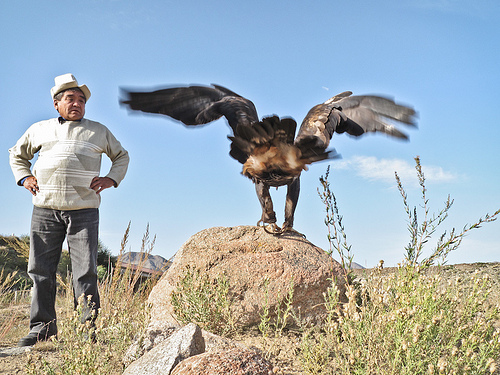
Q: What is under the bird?
A: Giant rock.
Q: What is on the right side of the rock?
A: Grass and plants.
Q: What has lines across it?
A: A white sweater.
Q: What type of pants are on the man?
A: Dark grey jean.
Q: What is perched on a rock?
A: A large bird.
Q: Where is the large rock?
A: On a desert floor.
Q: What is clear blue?
A: Sky.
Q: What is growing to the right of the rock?
A: A desert plant.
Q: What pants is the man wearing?
A: A pair of gray pants.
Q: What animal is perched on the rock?
A: Bird.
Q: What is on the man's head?
A: Hat.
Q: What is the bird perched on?
A: A rock.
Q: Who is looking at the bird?
A: A man.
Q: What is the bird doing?
A: Spreading wings.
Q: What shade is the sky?
A: Blue.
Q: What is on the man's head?
A: A hat.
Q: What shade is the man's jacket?
A: White.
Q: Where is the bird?
A: On a rock.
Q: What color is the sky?
A: Blue.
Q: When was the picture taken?
A: Daytime.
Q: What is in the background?
A: Mountains.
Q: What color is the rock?
A: Brown.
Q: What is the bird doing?
A: Spreading wings.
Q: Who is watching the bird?
A: The man on the left.